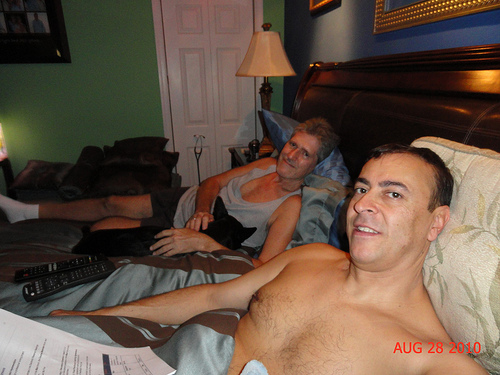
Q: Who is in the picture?
A: Two men.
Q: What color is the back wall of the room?
A: Green.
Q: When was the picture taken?
A: August 28, 2010.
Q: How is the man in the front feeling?
A: Happy.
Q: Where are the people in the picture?
A: In bed.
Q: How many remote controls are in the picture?
A: Two.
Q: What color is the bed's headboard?
A: Brown.